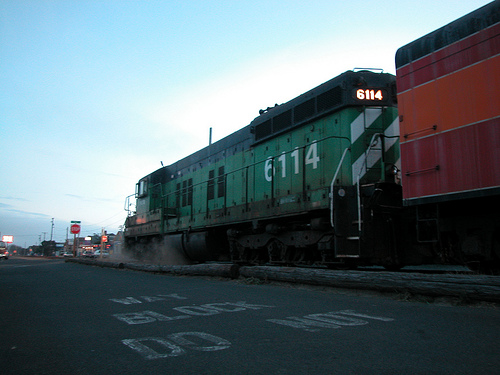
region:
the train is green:
[88, 94, 398, 235]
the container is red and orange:
[388, 17, 491, 210]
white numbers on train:
[246, 132, 341, 209]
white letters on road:
[91, 261, 414, 357]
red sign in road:
[66, 220, 91, 252]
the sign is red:
[61, 217, 93, 243]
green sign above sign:
[65, 210, 90, 230]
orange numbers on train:
[347, 75, 385, 111]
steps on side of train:
[316, 145, 380, 265]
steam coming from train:
[103, 210, 195, 278]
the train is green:
[144, 102, 420, 312]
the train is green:
[111, 148, 331, 366]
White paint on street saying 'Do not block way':
[99, 283, 394, 373]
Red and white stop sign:
[66, 220, 85, 252]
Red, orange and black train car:
[394, 8, 498, 211]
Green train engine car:
[122, 64, 392, 254]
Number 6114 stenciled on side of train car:
[255, 133, 335, 185]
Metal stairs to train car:
[325, 137, 407, 262]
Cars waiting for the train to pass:
[61, 232, 113, 276]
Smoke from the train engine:
[100, 222, 177, 272]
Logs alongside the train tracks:
[124, 253, 485, 309]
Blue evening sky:
[0, 115, 104, 252]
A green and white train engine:
[83, 60, 392, 265]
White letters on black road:
[87, 271, 407, 373]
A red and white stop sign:
[64, 225, 86, 257]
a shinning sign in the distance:
[3, 232, 17, 248]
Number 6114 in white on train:
[258, 146, 338, 183]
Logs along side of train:
[48, 233, 498, 308]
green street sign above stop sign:
[68, 216, 85, 224]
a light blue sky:
[3, 11, 231, 261]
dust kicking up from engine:
[107, 223, 192, 278]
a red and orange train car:
[380, 13, 498, 241]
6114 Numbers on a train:
[262, 139, 322, 183]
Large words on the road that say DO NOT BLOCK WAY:
[108, 290, 395, 363]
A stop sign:
[68, 223, 81, 258]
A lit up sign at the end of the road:
[1, 233, 14, 248]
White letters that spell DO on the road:
[118, 327, 232, 360]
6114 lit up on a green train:
[355, 85, 386, 103]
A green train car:
[123, 65, 406, 267]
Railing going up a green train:
[323, 131, 401, 262]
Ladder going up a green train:
[351, 66, 391, 185]